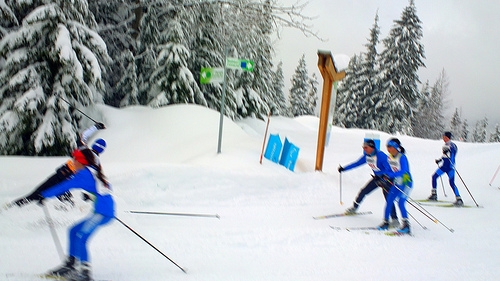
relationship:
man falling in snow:
[93, 137, 111, 173] [102, 105, 341, 275]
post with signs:
[194, 41, 254, 157] [196, 54, 258, 86]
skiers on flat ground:
[336, 128, 427, 236] [11, 163, 499, 275]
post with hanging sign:
[318, 72, 330, 173] [327, 75, 336, 142]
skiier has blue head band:
[377, 132, 417, 239] [386, 138, 402, 151]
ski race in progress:
[11, 163, 499, 275] [7, 117, 499, 276]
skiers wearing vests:
[7, 117, 499, 276] [89, 158, 406, 192]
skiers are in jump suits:
[7, 117, 499, 276] [48, 151, 488, 264]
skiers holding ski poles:
[336, 128, 427, 236] [395, 185, 459, 238]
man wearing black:
[0, 121, 110, 215] [14, 160, 70, 197]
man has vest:
[0, 121, 110, 215] [67, 155, 75, 170]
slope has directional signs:
[11, 163, 499, 275] [195, 45, 354, 176]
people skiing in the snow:
[7, 117, 499, 276] [11, 163, 499, 275]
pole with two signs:
[219, 66, 228, 153] [196, 54, 258, 86]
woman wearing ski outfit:
[377, 132, 417, 239] [375, 154, 414, 217]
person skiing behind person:
[423, 126, 471, 211] [34, 146, 123, 281]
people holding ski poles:
[7, 117, 499, 276] [406, 194, 455, 237]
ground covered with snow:
[11, 163, 499, 275] [102, 105, 341, 275]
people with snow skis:
[7, 117, 499, 276] [119, 200, 456, 270]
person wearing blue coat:
[377, 132, 417, 239] [376, 153, 416, 191]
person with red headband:
[37, 145, 123, 280] [67, 146, 92, 170]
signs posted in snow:
[196, 54, 258, 86] [102, 105, 341, 275]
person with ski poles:
[37, 145, 123, 280] [39, 197, 188, 280]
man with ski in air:
[0, 121, 110, 215] [48, 84, 111, 136]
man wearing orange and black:
[0, 121, 110, 215] [52, 155, 74, 175]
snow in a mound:
[102, 105, 341, 275] [131, 101, 244, 168]